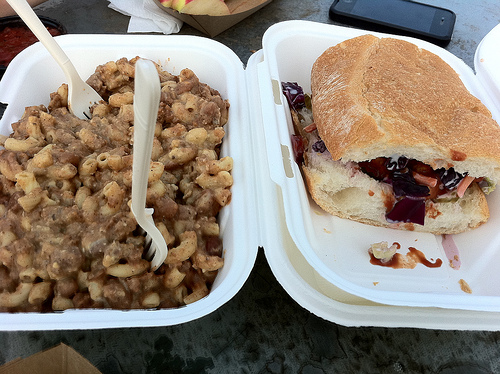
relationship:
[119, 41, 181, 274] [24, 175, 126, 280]
fork stuck in food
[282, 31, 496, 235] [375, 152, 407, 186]
sandwich on sauce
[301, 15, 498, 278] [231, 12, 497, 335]
sandwich on box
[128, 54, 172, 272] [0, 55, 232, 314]
fork in food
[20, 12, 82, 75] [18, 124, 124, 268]
fork in food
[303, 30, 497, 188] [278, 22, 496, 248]
top bread on sandwich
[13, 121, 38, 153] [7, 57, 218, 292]
noodle in casserole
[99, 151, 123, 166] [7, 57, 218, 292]
noodle in casserole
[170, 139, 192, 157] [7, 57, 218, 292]
noodle in casserole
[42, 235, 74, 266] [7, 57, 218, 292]
meat in casserole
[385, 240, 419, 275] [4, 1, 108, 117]
sauce in fork